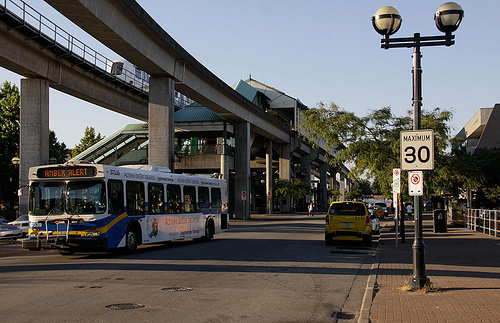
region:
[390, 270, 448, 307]
grass around the black sign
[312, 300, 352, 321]
stain on the street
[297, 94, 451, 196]
green tree spreading across the street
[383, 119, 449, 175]
white sign with black words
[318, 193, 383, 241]
yellow cab on street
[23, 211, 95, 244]
bike rack on front of bus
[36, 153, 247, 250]
passenger bus on the street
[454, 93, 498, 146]
top of tall silver building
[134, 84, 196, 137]
wide base on overhead station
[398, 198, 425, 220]
man walking on the street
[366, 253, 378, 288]
edge of a road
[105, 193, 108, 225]
edge of a bus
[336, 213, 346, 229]
back of a car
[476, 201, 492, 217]
part of a fence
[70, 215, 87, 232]
front of a car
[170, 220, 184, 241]
side of a bus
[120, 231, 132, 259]
part of a wheel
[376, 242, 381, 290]
edge of a pavement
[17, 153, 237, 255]
blue, yellow, and white bus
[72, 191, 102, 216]
bus driver wearing sunglasses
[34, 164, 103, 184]
orange letters on front of bus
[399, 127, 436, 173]
white and black speed limit sign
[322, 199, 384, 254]
yellow car parked near the sidewalk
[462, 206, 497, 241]
thick iron railing on sidewalk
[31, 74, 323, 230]
large metro rail bridge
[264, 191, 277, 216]
red and white stop sign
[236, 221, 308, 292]
shadow lines on the street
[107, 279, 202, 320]
two sewer opening on the street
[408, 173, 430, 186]
red circle on sign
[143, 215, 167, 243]
small logo on side of bus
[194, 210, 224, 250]
black wheel in bus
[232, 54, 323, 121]
roof on top of train station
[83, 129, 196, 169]
steps leading up to station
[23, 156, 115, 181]
yellow wording on front of bus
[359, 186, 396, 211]
white van in street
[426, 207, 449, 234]
trash can on the side walk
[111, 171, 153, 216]
window in the passenger bus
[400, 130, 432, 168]
White speed limit sign with black letters.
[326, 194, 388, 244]
Vehicles are parked along thestreet in front of yellow car.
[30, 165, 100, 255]
Bus has Amber Alert sign on top.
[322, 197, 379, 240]
Yellow car is parked next to the curb.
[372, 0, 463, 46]
Two round street lights are on top of post.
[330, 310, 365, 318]
Metal drain is next to curb on right.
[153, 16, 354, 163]
A long elevated structure comes from building in rear.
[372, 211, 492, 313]
The sidewalk is paved with bricks.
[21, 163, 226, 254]
A city bus is white with blue and yellow stripes.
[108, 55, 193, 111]
An elevated train is behind the railing and nearby structure.